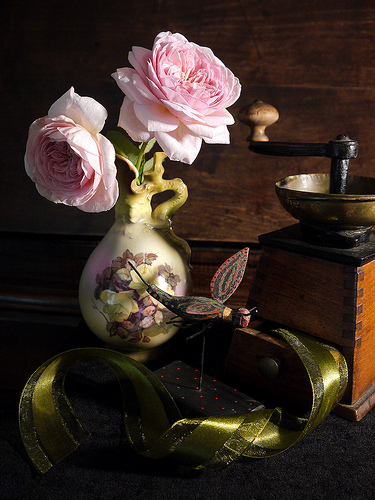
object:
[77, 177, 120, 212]
flower petal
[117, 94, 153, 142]
flower petal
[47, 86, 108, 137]
flower petal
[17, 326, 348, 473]
ribbon strip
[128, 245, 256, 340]
bug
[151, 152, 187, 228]
handle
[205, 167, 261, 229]
grain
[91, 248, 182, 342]
decoration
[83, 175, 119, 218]
petal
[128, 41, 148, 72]
petal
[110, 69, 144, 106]
petal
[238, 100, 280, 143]
wood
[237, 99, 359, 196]
grinding mill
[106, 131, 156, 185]
leaf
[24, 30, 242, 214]
plant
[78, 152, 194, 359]
vase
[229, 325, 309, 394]
drawer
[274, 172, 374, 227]
bowl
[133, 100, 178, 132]
flower petal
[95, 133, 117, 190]
flower petal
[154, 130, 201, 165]
flower petal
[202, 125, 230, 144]
flower petal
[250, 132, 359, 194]
crank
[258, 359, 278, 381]
knob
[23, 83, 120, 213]
flower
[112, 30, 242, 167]
flower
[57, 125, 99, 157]
petal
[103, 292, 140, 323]
flower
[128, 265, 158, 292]
flower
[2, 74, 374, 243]
wood